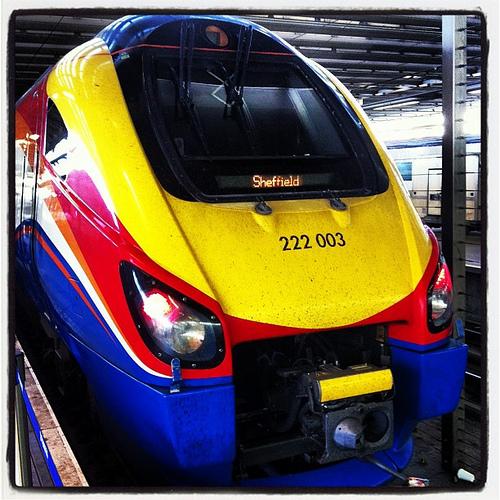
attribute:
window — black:
[116, 27, 388, 209]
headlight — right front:
[125, 278, 215, 363]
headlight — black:
[141, 289, 205, 357]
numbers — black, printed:
[276, 228, 350, 253]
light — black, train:
[131, 274, 224, 369]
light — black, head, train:
[414, 255, 473, 324]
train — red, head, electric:
[12, 14, 472, 484]